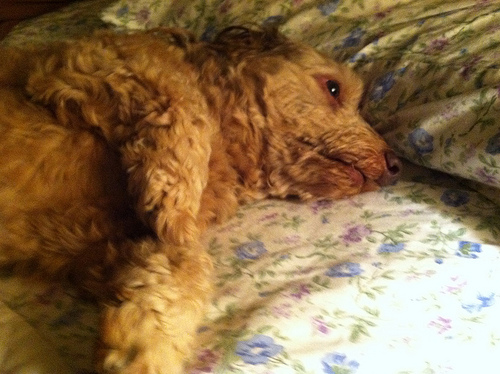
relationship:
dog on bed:
[1, 25, 404, 371] [247, 198, 499, 373]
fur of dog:
[157, 26, 292, 81] [1, 25, 404, 371]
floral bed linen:
[233, 235, 274, 265] [231, 204, 499, 374]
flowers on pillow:
[405, 35, 486, 156] [402, 0, 499, 161]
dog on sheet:
[1, 25, 404, 371] [243, 204, 499, 374]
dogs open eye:
[1, 25, 404, 371] [327, 79, 341, 99]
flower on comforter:
[235, 335, 282, 366] [231, 204, 499, 374]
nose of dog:
[382, 151, 403, 186] [1, 25, 404, 371]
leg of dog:
[34, 49, 211, 244] [1, 25, 404, 371]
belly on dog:
[3, 129, 104, 264] [1, 25, 404, 371]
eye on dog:
[327, 79, 341, 99] [1, 25, 404, 371]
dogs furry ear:
[1, 25, 404, 371] [216, 19, 287, 54]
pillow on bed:
[402, 0, 499, 161] [247, 198, 499, 373]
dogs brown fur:
[1, 25, 404, 371] [1, 26, 285, 239]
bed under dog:
[247, 198, 499, 373] [1, 25, 404, 371]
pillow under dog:
[402, 0, 499, 161] [1, 25, 404, 371]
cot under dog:
[247, 198, 499, 373] [1, 25, 404, 371]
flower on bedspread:
[235, 335, 282, 366] [243, 204, 499, 374]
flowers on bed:
[405, 35, 486, 156] [247, 198, 499, 373]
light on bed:
[300, 244, 497, 373] [247, 198, 499, 373]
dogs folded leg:
[1, 25, 404, 371] [34, 49, 211, 244]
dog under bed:
[1, 25, 404, 371] [247, 198, 499, 373]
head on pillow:
[216, 23, 401, 197] [402, 0, 499, 161]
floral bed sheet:
[233, 235, 274, 265] [243, 204, 499, 374]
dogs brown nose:
[1, 25, 404, 371] [382, 151, 403, 186]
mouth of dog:
[319, 154, 369, 191] [1, 25, 404, 371]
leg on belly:
[34, 49, 211, 244] [3, 129, 104, 264]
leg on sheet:
[82, 241, 207, 373] [243, 204, 499, 374]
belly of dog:
[3, 129, 104, 264] [1, 25, 404, 371]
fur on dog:
[1, 26, 285, 239] [1, 25, 404, 371]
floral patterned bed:
[233, 235, 274, 265] [247, 198, 499, 373]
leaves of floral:
[205, 257, 284, 288] [233, 235, 269, 262]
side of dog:
[1, 39, 127, 273] [1, 25, 404, 371]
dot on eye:
[330, 87, 335, 93] [327, 79, 341, 99]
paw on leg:
[127, 170, 199, 239] [34, 49, 211, 244]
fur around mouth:
[268, 124, 315, 200] [319, 154, 369, 191]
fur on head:
[157, 26, 292, 81] [216, 23, 401, 197]